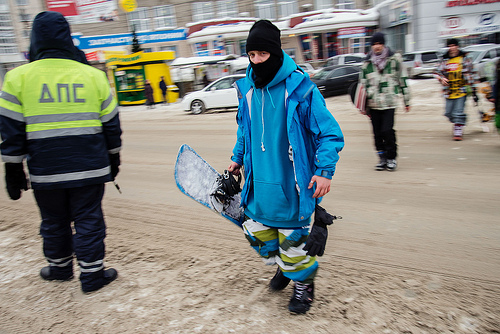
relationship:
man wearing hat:
[1, 10, 122, 293] [26, 9, 73, 51]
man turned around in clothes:
[1, 10, 122, 293] [0, 47, 121, 273]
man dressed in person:
[1, 10, 121, 297] [198, 9, 345, 318]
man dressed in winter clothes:
[1, 10, 121, 297] [220, 18, 340, 315]